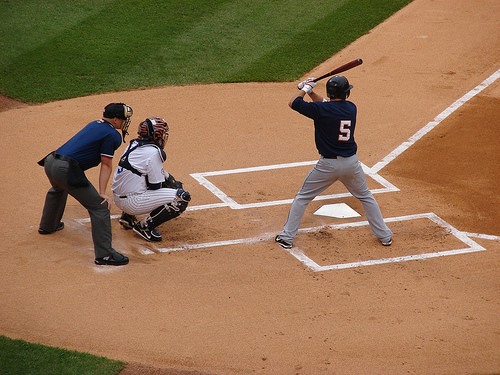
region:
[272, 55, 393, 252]
A baseball player batting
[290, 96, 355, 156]
Number "5" blue jersey on a batter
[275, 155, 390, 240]
Gray pants on a batter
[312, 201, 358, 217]
Home plate on a baseball field.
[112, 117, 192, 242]
A baseball catcher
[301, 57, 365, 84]
A brown baseball bat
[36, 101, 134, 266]
Baseball umpire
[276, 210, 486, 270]
Left handers batter's box on a baseball field.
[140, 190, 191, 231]
Catcher's shin guard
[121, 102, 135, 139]
Umpire's mask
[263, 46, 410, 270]
Batter has a bat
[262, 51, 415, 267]
Batter has a bat on left side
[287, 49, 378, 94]
Bat is made of wood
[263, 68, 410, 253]
Batter had blue shirt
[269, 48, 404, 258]
Batter has grey pants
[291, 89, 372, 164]
Shirt has number 5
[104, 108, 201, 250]
Catcher is crouched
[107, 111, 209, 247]
Catcher has white cloths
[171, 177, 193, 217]
Catcher wears kneepads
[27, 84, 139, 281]
Man has blue shirt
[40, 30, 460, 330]
baseball game is underway.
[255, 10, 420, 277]
baseball player with bat.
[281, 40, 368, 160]
person holding a baseball bat.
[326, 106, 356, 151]
number "five" showing on uniform.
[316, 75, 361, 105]
person wearing a dark helmet.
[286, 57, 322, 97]
two hands holding a bat.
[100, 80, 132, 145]
person wearing face protection.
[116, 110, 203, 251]
catcher in squatting position.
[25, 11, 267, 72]
green patch of grass.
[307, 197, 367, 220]
base plate on the ground.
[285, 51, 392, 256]
baseball player waiting for pitch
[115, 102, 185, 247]
baseball catcher waiting for pitch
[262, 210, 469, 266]
batter's box on baseball field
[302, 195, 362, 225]
home plate on baseball field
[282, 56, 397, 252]
left-handed batter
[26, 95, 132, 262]
umpire waiting for pitch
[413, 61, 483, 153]
foul line on baseball field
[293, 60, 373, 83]
baseball bat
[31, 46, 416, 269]
waiting on pitch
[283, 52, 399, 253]
batter in hitting stance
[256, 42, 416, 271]
A man with a bat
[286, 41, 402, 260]
A man playing baseball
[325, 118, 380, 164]
The number 5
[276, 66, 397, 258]
A man in light grey pants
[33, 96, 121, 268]
A man in dark grey pants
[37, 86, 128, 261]
A man in a blue shirt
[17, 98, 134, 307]
A baseball umpire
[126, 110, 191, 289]
A baseball catcher in white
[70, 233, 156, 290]
A shoe on a foot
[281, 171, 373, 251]
Home plate